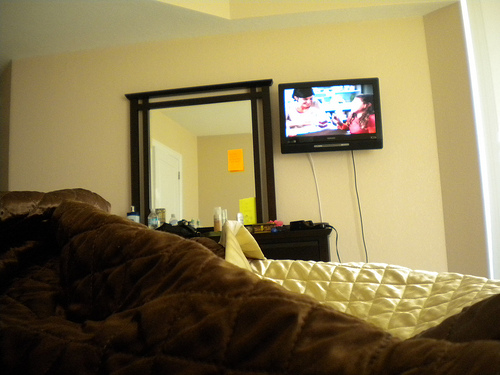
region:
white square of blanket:
[387, 307, 422, 325]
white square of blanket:
[418, 303, 445, 320]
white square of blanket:
[450, 293, 472, 306]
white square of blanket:
[368, 313, 389, 327]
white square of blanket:
[367, 298, 397, 315]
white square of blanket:
[396, 298, 424, 310]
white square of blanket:
[421, 290, 451, 303]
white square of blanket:
[266, 260, 291, 279]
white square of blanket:
[288, 263, 312, 276]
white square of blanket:
[308, 261, 333, 279]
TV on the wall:
[270, 65, 385, 155]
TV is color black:
[272, 65, 387, 155]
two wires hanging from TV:
[297, 135, 369, 225]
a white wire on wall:
[305, 150, 330, 215]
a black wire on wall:
[341, 150, 376, 235]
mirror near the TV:
[119, 70, 287, 235]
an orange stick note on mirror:
[220, 142, 250, 176]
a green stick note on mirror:
[234, 191, 257, 226]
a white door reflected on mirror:
[143, 133, 188, 220]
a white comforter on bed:
[223, 247, 498, 342]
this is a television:
[258, 61, 400, 161]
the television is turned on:
[265, 65, 417, 162]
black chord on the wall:
[328, 141, 388, 256]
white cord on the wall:
[296, 155, 343, 253]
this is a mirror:
[106, 70, 293, 241]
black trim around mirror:
[119, 75, 308, 247]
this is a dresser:
[138, 210, 355, 270]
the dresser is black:
[142, 200, 359, 290]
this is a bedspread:
[40, 190, 385, 373]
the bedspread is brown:
[37, 194, 328, 366]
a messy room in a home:
[27, 6, 426, 333]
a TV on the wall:
[273, 60, 410, 152]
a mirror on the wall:
[115, 67, 288, 234]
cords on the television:
[293, 145, 383, 247]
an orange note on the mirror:
[217, 145, 254, 175]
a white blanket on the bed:
[238, 246, 499, 340]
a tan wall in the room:
[26, 60, 118, 175]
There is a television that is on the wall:
[302, 78, 364, 145]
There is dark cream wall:
[399, 168, 425, 217]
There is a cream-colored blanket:
[357, 275, 367, 311]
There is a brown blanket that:
[142, 245, 152, 309]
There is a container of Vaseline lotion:
[123, 200, 138, 231]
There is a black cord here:
[343, 183, 376, 213]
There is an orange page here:
[231, 150, 245, 196]